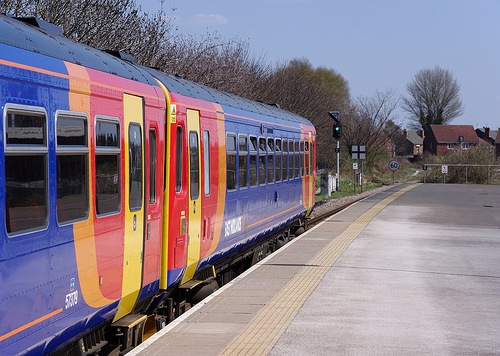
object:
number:
[62, 292, 71, 310]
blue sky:
[118, 0, 499, 133]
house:
[394, 125, 425, 157]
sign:
[386, 159, 399, 172]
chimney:
[401, 128, 408, 139]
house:
[419, 124, 479, 163]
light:
[326, 110, 344, 192]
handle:
[146, 222, 151, 239]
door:
[141, 104, 166, 288]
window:
[223, 149, 240, 192]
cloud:
[155, 12, 228, 27]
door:
[111, 91, 146, 326]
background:
[0, 0, 499, 354]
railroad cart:
[0, 14, 317, 355]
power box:
[319, 171, 333, 196]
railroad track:
[305, 180, 403, 227]